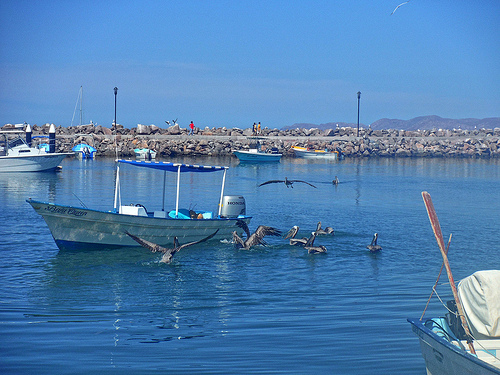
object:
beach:
[0, 125, 499, 158]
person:
[188, 120, 195, 135]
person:
[251, 122, 257, 135]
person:
[256, 121, 263, 136]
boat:
[232, 146, 283, 162]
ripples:
[132, 274, 319, 354]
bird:
[121, 227, 221, 264]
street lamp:
[111, 85, 120, 95]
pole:
[112, 97, 119, 127]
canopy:
[110, 158, 230, 224]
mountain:
[367, 112, 497, 134]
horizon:
[0, 121, 500, 133]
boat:
[0, 122, 82, 173]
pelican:
[257, 177, 319, 190]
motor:
[218, 191, 246, 221]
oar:
[415, 189, 481, 336]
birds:
[367, 231, 387, 253]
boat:
[26, 157, 256, 251]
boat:
[406, 189, 500, 375]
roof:
[116, 158, 229, 175]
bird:
[257, 176, 319, 191]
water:
[2, 156, 498, 372]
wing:
[183, 228, 221, 248]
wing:
[120, 228, 163, 254]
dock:
[1, 139, 76, 160]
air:
[1, 0, 499, 373]